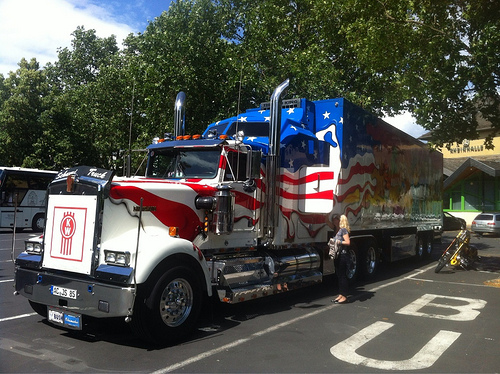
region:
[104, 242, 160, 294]
a semi trucks headlights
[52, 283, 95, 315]
the semi trucks tag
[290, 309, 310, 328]
a white line on the ground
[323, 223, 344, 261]
a woman holding something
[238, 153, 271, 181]
the semi truck rear view mirrior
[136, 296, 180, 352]
a semi trucks tire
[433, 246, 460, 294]
a motorcycles black tire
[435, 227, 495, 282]
a motorcycle parked near semi truck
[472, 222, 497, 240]
a grey car near the semi and motorcycle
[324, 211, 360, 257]
a women checking semi truck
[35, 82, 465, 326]
Huge semi truck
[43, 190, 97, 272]
Logo with KW on the front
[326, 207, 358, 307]
Woman standing next to the truck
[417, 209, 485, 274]
Parked motorcycle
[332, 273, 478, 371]
Letters BU on the ground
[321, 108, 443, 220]
Painted mural on side of the bus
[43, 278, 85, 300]
License plate AC 25 85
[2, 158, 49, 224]
White bus on the left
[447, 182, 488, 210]
Building with green pillars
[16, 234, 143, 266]
Four headlights that are turned off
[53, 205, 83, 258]
a red KW logo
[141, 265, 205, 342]
a dark black rubber tire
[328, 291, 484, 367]
white writing on a parking lot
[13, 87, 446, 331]
a very american 18 wheeler truck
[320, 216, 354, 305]
a blond woman standing by a truck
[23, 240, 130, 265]
headlights on the front of a truck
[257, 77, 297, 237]
a chrome exhaust on a truck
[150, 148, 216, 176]
the front windshield to a truck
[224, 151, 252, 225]
a driver side door to a truck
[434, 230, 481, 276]
a parked motorcycle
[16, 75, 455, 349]
truck painted in red, white and blue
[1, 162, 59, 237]
bus parked in a parking lot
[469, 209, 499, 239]
back of a gray car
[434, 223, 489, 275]
motorcycle parked beside a truck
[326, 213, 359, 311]
blonde woman standing next to a truck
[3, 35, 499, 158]
dark green leaves of trees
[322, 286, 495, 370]
white letters painted on the cement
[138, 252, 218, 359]
front tire of a truck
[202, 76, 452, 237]
semi-trailer painted like a flag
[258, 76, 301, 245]
large silver exhaust pipe on truck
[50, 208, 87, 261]
A red KW logo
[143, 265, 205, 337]
a black rubber tire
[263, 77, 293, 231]
a large chrome exhaust pipe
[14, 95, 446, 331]
a large american 18 wheeler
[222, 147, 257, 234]
the driver side door to a truck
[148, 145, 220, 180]
a trucks front windshield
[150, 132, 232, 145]
a row of lights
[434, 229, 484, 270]
a motorcycle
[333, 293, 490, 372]
writing on a parking lot